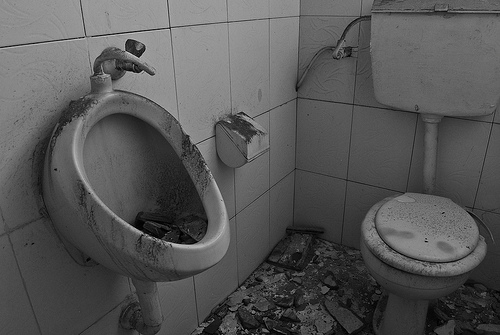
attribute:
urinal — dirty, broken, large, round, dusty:
[39, 71, 230, 281]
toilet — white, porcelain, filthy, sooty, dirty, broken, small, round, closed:
[360, 191, 487, 334]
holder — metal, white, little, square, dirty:
[216, 112, 268, 170]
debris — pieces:
[197, 233, 497, 334]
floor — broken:
[192, 233, 500, 334]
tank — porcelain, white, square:
[369, 0, 498, 119]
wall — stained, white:
[0, 2, 499, 334]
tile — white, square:
[4, 3, 496, 334]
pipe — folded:
[117, 277, 164, 334]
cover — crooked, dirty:
[375, 193, 479, 262]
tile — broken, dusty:
[194, 230, 499, 334]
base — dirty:
[379, 291, 430, 334]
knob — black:
[124, 39, 145, 55]